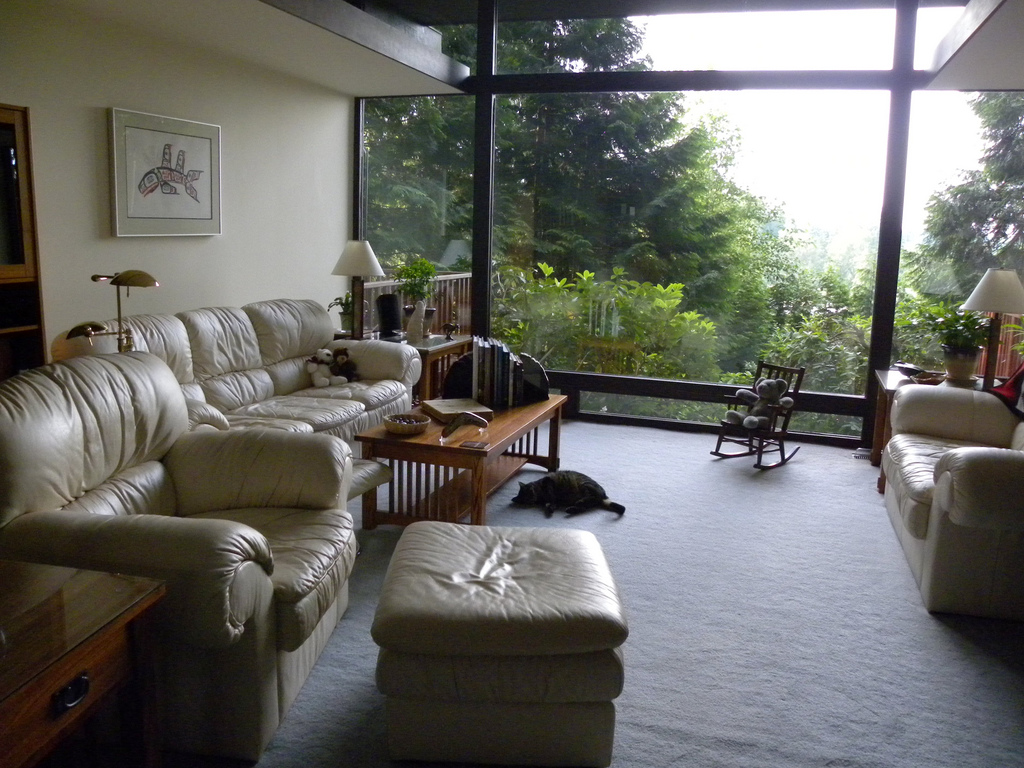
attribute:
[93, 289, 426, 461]
sofa — creamed color , leather 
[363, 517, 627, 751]
ottoman — leather , cream color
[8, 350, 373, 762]
armchair — cream color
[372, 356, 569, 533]
coffee table — wooden , brown 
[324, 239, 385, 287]
lamp shade — white 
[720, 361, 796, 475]
rocking chair — small 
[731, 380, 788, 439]
stuffed animal — stuffed 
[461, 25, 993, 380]
trees — Green , leafy 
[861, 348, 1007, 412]
table — small 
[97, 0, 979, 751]
living room — big 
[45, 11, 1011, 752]
room — big 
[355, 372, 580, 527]
table — wooden 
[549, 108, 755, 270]
tree — large, green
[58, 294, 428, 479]
sofa — large , white 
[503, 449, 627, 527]
cat — black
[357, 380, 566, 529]
coffee table — wooden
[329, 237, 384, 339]
lamp shade — white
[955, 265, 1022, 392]
lamp shade — white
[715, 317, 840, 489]
chair — wooden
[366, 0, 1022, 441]
window — large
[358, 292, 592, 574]
table — wooden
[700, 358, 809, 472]
chair — small 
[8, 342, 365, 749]
chair — large , white 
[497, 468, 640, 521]
cat — black 